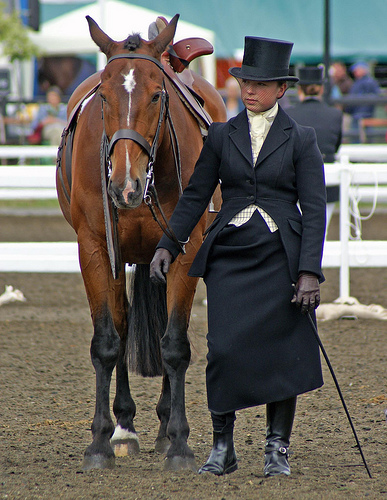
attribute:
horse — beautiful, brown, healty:
[49, 21, 210, 457]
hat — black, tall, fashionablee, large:
[209, 20, 306, 109]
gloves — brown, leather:
[133, 250, 325, 323]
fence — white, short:
[4, 140, 60, 278]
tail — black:
[117, 256, 168, 383]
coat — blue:
[158, 108, 348, 293]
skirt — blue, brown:
[192, 210, 334, 405]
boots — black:
[192, 371, 303, 479]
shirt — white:
[243, 112, 270, 154]